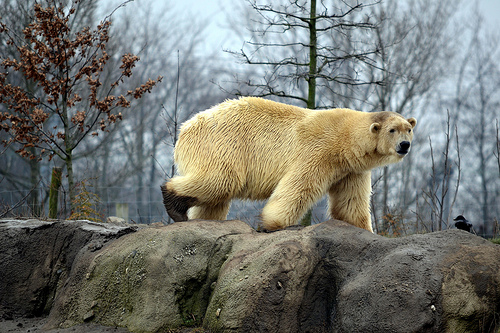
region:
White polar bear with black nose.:
[159, 95, 416, 230]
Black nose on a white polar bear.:
[398, 140, 413, 151]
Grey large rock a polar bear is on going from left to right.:
[1, 215, 498, 332]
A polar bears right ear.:
[368, 122, 380, 132]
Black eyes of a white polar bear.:
[389, 126, 414, 133]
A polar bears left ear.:
[407, 113, 418, 130]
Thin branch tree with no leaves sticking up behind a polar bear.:
[223, 1, 395, 108]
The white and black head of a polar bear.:
[376, 110, 414, 157]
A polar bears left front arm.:
[328, 168, 373, 233]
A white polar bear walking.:
[158, 95, 416, 232]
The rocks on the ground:
[91, 246, 463, 320]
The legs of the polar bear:
[253, 178, 380, 237]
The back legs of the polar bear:
[158, 169, 238, 226]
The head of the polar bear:
[366, 100, 421, 170]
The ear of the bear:
[364, 117, 383, 137]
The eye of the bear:
[385, 123, 400, 136]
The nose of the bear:
[396, 138, 412, 151]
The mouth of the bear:
[392, 145, 410, 158]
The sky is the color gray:
[119, 8, 289, 76]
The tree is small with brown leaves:
[13, 10, 149, 208]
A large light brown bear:
[148, 64, 421, 236]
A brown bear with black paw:
[160, 175, 202, 219]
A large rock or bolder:
[92, 202, 425, 311]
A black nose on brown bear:
[385, 128, 423, 165]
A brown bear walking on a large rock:
[123, 90, 431, 306]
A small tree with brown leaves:
[14, 8, 134, 185]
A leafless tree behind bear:
[241, 3, 405, 107]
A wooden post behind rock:
[41, 155, 76, 230]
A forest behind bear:
[101, 29, 445, 194]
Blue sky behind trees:
[189, 6, 271, 63]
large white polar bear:
[112, 69, 422, 216]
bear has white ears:
[370, 111, 430, 143]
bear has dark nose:
[380, 126, 412, 179]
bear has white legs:
[212, 173, 375, 244]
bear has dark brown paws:
[160, 169, 208, 223]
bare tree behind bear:
[249, 24, 401, 118]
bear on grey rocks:
[22, 196, 481, 326]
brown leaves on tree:
[1, 11, 156, 177]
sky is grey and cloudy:
[142, 16, 272, 76]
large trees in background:
[124, 11, 493, 150]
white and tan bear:
[163, 98, 417, 231]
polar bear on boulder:
[170, 98, 415, 227]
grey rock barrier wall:
[1, 222, 498, 332]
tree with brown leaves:
[3, 5, 160, 211]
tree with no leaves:
[243, 2, 390, 106]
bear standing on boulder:
[153, 93, 417, 234]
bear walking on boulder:
[166, 96, 417, 232]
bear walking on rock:
[166, 98, 418, 234]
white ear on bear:
[370, 122, 380, 135]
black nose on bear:
[398, 139, 410, 149]